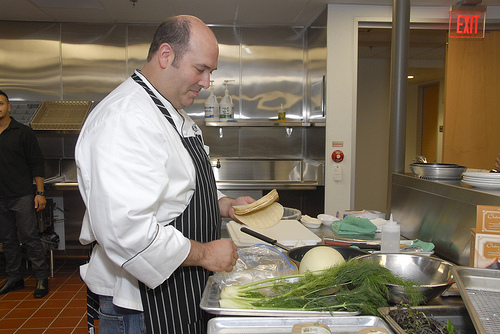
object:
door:
[442, 31, 500, 175]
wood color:
[439, 29, 499, 170]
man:
[73, 15, 269, 334]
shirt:
[72, 68, 222, 312]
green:
[347, 271, 360, 277]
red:
[47, 299, 62, 304]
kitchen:
[0, 0, 499, 332]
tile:
[41, 298, 71, 309]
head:
[143, 13, 219, 109]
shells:
[234, 201, 284, 230]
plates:
[461, 171, 499, 177]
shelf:
[384, 154, 500, 270]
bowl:
[347, 251, 459, 306]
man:
[0, 90, 52, 299]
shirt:
[0, 117, 46, 200]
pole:
[384, 0, 409, 219]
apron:
[134, 71, 220, 333]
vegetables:
[388, 311, 457, 334]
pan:
[286, 244, 371, 264]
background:
[0, 0, 499, 334]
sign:
[449, 9, 484, 37]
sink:
[42, 127, 328, 265]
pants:
[0, 194, 50, 279]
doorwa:
[356, 24, 499, 215]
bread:
[231, 188, 284, 229]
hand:
[227, 194, 257, 225]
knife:
[238, 224, 290, 250]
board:
[227, 218, 322, 246]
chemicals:
[255, 90, 300, 111]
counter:
[203, 116, 330, 127]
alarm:
[330, 149, 342, 164]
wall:
[322, 2, 357, 221]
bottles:
[203, 79, 221, 122]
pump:
[207, 80, 216, 92]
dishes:
[317, 213, 342, 225]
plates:
[410, 160, 467, 181]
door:
[419, 84, 439, 165]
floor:
[0, 249, 96, 333]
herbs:
[218, 255, 425, 314]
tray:
[200, 272, 367, 315]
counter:
[215, 213, 468, 333]